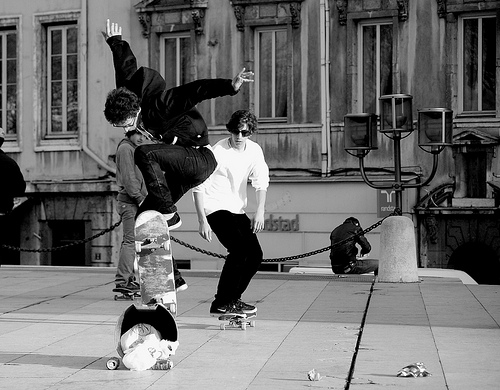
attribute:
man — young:
[192, 100, 279, 317]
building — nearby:
[3, 7, 483, 277]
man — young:
[89, 29, 224, 224]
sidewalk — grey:
[0, 253, 481, 389]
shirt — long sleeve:
[189, 139, 276, 218]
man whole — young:
[189, 103, 276, 327]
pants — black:
[197, 202, 259, 317]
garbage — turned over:
[106, 292, 200, 368]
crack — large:
[345, 280, 374, 387]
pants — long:
[209, 207, 261, 349]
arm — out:
[101, 17, 139, 87]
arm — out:
[163, 67, 254, 106]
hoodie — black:
[100, 38, 232, 213]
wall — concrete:
[293, 259, 481, 284]